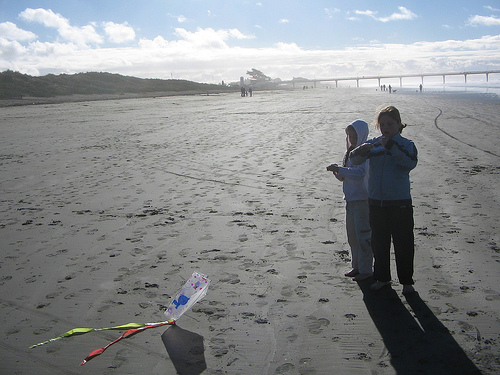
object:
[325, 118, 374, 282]
child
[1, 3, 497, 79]
sky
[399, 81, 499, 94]
water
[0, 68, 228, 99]
hill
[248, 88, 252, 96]
person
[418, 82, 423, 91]
person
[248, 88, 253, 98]
family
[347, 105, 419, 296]
barefoot girls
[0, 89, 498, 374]
beach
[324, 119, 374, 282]
family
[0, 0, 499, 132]
background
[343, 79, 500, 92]
ocean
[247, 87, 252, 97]
people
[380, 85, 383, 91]
people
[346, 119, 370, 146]
hood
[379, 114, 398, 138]
face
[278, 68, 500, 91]
bridge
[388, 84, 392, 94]
friends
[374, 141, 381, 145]
stripes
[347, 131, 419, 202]
jacket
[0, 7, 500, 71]
clouds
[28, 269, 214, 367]
kite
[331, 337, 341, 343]
foot prints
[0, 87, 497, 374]
sand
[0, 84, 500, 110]
horizon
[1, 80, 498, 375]
ground